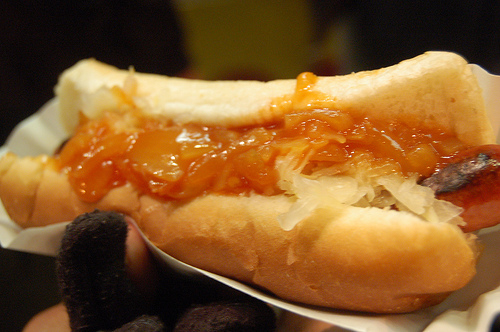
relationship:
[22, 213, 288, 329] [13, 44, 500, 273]
person holding hot dog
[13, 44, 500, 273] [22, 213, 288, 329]
hot dog in person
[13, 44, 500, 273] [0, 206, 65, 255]
hot dog in paper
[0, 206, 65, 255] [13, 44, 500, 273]
paper around hot dog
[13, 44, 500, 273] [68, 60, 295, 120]
hot dog between bread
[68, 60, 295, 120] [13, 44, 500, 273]
bread around hot dog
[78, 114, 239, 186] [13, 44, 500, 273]
sauce over hot dog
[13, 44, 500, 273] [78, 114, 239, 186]
hot dog under sauce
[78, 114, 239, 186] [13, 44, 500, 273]
sauce kept over hot dog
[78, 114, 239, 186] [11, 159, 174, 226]
sauce on bun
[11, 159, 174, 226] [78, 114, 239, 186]
bun under sauce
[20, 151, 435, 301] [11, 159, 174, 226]
half of bun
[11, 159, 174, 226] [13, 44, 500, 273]
bun of hot dog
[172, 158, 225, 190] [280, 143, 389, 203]
pieces of sauerkraut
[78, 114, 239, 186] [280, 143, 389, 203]
sauce on sauerkraut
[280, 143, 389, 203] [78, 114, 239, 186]
sauerkraut under sauce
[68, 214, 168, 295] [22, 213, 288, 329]
finger of person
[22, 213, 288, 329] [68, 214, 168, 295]
person has finger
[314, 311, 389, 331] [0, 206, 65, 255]
piece of paper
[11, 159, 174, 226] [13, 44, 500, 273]
bun for hot dog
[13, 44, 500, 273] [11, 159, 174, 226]
hot dog has bun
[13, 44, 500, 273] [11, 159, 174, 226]
hot dog with bun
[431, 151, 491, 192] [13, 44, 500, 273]
spot on hot dog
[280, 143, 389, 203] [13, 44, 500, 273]
sauerkraut on hot dog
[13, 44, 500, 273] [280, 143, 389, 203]
hot dog with sauerkraut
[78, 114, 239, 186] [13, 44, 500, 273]
sauce on hot dog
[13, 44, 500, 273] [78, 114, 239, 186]
hot dog with sauce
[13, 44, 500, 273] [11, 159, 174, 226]
hot dog on bun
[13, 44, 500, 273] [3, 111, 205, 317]
hot dog in wrapper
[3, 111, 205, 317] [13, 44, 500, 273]
wrapper around hot dog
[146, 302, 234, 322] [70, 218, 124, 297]
part of glove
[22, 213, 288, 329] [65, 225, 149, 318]
someone wearing gloves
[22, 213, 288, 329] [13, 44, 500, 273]
someone holding hot dog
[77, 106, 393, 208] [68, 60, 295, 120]
toppings on bread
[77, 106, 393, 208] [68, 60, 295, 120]
toppings in middle of bread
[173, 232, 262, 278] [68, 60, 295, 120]
crust on bread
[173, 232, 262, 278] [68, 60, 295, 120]
crust outside of bread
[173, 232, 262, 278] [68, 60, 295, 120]
crust on outside of bread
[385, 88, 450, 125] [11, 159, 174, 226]
inside of bun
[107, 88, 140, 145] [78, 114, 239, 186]
onions in sauce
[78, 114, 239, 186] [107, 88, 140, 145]
sauce with onions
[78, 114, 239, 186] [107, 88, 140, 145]
sauce has onions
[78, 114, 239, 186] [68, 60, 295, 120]
sauce over bread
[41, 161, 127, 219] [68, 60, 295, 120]
side of bread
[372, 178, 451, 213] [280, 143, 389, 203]
shreds of sauerkraut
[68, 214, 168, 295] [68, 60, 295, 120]
finger on bread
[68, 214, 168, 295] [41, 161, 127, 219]
finger on side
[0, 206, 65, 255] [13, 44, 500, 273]
paper underneath hot dog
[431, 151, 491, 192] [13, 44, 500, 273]
mark on hot dog